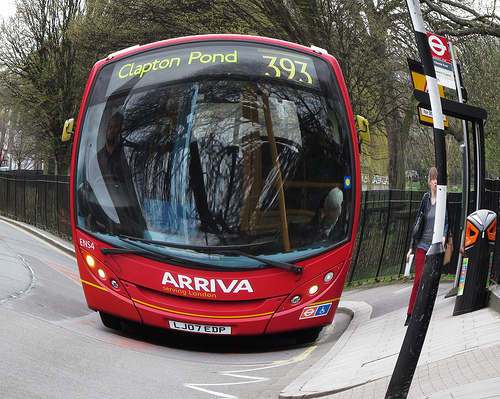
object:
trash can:
[450, 208, 497, 316]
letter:
[232, 278, 257, 293]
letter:
[210, 51, 224, 66]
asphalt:
[0, 218, 349, 398]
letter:
[223, 47, 240, 65]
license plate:
[168, 320, 230, 335]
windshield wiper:
[225, 247, 303, 275]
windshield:
[75, 77, 355, 267]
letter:
[187, 51, 202, 67]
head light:
[320, 272, 334, 284]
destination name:
[117, 48, 243, 78]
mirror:
[355, 110, 371, 144]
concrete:
[314, 341, 499, 399]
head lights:
[83, 253, 98, 269]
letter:
[198, 52, 213, 66]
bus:
[60, 30, 373, 341]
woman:
[403, 165, 449, 328]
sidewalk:
[274, 282, 498, 399]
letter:
[117, 60, 128, 79]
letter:
[125, 61, 135, 79]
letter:
[134, 63, 143, 75]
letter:
[137, 60, 151, 78]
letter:
[149, 59, 157, 72]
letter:
[157, 58, 170, 70]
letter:
[168, 56, 184, 70]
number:
[261, 56, 283, 79]